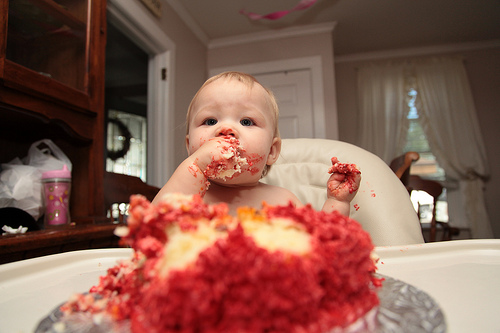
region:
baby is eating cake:
[127, 53, 370, 245]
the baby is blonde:
[111, 53, 367, 245]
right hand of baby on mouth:
[138, 60, 371, 247]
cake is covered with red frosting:
[83, 182, 382, 329]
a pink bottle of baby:
[33, 155, 75, 237]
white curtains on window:
[339, 45, 499, 243]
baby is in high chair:
[12, 64, 492, 331]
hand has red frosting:
[316, 153, 368, 213]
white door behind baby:
[190, 53, 332, 175]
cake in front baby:
[63, 55, 400, 328]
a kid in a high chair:
[152, 100, 366, 321]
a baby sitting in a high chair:
[146, 30, 394, 330]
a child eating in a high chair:
[119, 82, 387, 330]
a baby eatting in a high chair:
[108, 53, 418, 330]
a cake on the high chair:
[141, 141, 478, 327]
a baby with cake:
[179, 93, 331, 257]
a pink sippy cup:
[26, 155, 91, 257]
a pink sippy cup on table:
[37, 143, 102, 235]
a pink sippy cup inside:
[7, 158, 142, 259]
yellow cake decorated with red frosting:
[120, 193, 378, 329]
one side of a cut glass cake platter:
[371, 275, 441, 330]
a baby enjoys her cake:
[180, 70, 275, 180]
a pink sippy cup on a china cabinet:
[35, 160, 70, 220]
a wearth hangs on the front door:
[100, 110, 125, 150]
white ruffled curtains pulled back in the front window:
[360, 50, 485, 225]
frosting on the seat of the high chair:
[350, 175, 380, 215]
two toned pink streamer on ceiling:
[223, 0, 319, 23]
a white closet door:
[216, 57, 328, 138]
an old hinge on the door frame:
[158, 61, 169, 85]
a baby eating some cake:
[148, 66, 363, 211]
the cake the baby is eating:
[31, 191, 441, 327]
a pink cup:
[40, 161, 71, 226]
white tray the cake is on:
[0, 237, 497, 327]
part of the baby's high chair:
[256, 135, 421, 242]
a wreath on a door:
[105, 112, 130, 157]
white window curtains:
[352, 55, 484, 235]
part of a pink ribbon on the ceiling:
[237, 0, 312, 20]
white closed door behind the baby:
[207, 52, 322, 132]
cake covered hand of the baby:
[322, 155, 362, 201]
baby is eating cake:
[152, 60, 272, 187]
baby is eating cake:
[159, 62, 285, 201]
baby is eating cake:
[162, 64, 269, 214]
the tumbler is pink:
[30, 165, 80, 245]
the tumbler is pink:
[22, 148, 87, 232]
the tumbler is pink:
[28, 142, 101, 252]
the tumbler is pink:
[27, 153, 83, 249]